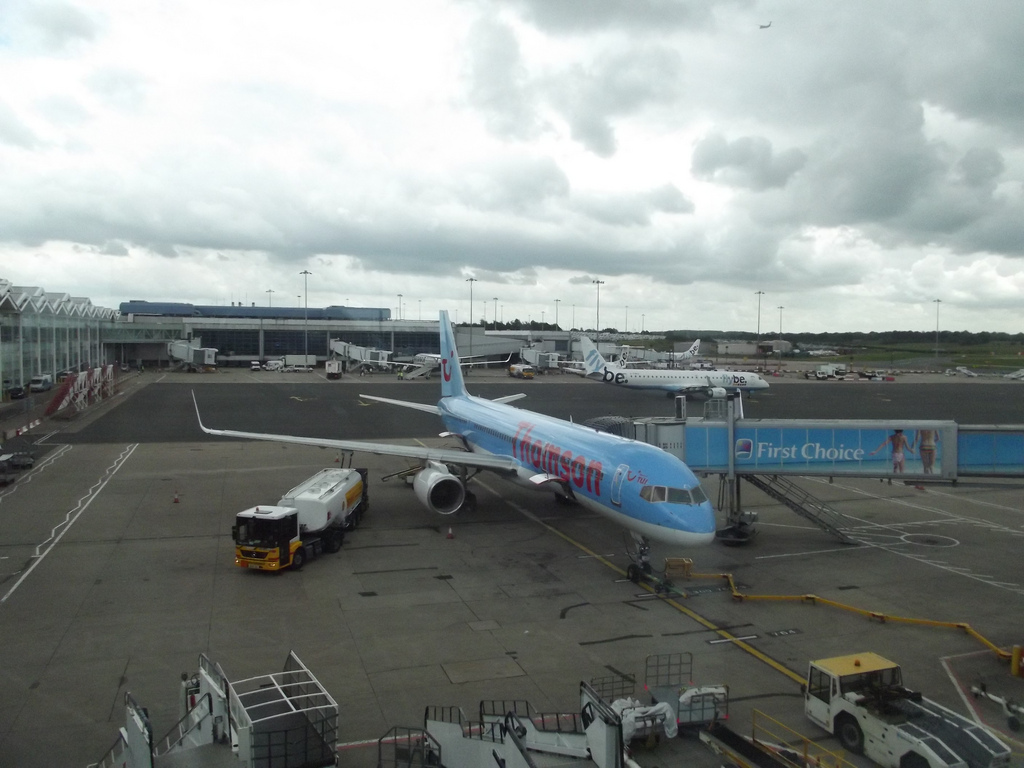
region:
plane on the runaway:
[397, 310, 729, 557]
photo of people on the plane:
[879, 423, 944, 482]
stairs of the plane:
[108, 696, 248, 764]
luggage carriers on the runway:
[626, 695, 760, 766]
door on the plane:
[605, 449, 629, 516]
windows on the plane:
[634, 464, 711, 521]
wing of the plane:
[210, 404, 493, 481]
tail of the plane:
[424, 291, 475, 409]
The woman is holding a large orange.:
[503, 649, 530, 716]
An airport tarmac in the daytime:
[5, 3, 1018, 757]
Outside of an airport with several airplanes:
[2, 7, 1014, 754]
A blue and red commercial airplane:
[410, 312, 725, 560]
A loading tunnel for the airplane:
[644, 410, 1022, 483]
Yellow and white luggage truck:
[221, 458, 373, 582]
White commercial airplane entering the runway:
[566, 329, 778, 393]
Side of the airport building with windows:
[3, 284, 453, 374]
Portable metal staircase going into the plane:
[746, 468, 873, 552]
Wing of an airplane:
[174, 379, 507, 506]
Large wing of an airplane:
[177, 386, 526, 501]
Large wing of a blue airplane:
[182, 382, 521, 513]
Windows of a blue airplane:
[638, 481, 706, 511]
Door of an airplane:
[610, 459, 631, 507]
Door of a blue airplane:
[610, 462, 631, 511]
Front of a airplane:
[602, 438, 721, 550]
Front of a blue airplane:
[630, 454, 722, 566]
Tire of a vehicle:
[294, 543, 308, 569]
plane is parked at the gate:
[174, 301, 747, 592]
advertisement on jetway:
[682, 421, 954, 472]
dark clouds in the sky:
[5, 4, 1023, 327]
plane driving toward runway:
[534, 329, 778, 415]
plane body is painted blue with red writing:
[427, 307, 726, 535]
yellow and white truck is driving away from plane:
[227, 455, 374, 577]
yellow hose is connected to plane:
[653, 549, 1011, 680]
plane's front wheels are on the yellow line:
[625, 552, 661, 595]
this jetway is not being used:
[166, 331, 223, 370]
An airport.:
[14, 260, 1010, 766]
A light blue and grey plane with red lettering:
[194, 322, 760, 580]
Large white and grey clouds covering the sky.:
[2, 7, 1021, 328]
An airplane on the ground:
[561, 336, 800, 413]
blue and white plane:
[289, 293, 710, 541]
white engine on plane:
[392, 471, 470, 520]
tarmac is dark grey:
[321, 559, 587, 766]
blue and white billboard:
[658, 398, 956, 479]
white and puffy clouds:
[342, 18, 798, 216]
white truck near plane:
[187, 474, 371, 582]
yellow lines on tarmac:
[737, 506, 912, 687]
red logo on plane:
[476, 386, 672, 511]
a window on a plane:
[638, 482, 648, 503]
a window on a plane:
[649, 479, 666, 503]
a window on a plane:
[664, 485, 691, 508]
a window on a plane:
[626, 370, 634, 384]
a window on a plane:
[635, 374, 639, 382]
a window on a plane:
[643, 374, 648, 382]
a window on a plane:
[667, 371, 671, 384]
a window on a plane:
[684, 374, 685, 384]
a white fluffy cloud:
[751, 209, 794, 264]